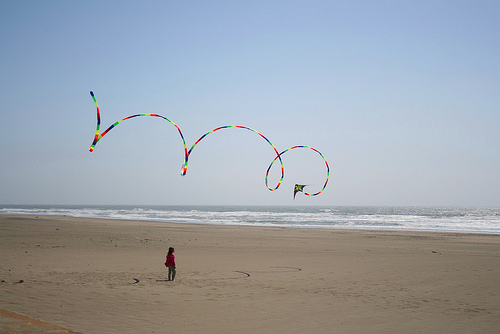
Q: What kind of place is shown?
A: It is a beach.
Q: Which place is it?
A: It is a beach.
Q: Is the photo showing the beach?
A: Yes, it is showing the beach.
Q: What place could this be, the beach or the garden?
A: It is the beach.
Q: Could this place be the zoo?
A: No, it is the beach.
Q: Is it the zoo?
A: No, it is the beach.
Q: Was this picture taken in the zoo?
A: No, the picture was taken in the beach.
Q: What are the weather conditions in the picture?
A: It is clear.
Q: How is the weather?
A: It is clear.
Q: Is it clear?
A: Yes, it is clear.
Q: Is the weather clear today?
A: Yes, it is clear.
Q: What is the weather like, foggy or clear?
A: It is clear.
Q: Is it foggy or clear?
A: It is clear.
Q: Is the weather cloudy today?
A: No, it is clear.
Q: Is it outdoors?
A: Yes, it is outdoors.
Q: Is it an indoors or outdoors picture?
A: It is outdoors.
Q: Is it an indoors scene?
A: No, it is outdoors.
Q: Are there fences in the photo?
A: No, there are no fences.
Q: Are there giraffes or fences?
A: No, there are no fences or giraffes.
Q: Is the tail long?
A: Yes, the tail is long.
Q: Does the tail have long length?
A: Yes, the tail is long.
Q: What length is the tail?
A: The tail is long.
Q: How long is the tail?
A: The tail is long.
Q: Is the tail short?
A: No, the tail is long.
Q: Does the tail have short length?
A: No, the tail is long.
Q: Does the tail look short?
A: No, the tail is long.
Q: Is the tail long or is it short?
A: The tail is long.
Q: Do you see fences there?
A: No, there are no fences.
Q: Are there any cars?
A: No, there are no cars.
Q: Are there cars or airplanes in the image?
A: No, there are no cars or airplanes.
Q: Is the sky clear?
A: Yes, the sky is clear.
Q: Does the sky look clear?
A: Yes, the sky is clear.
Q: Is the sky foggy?
A: No, the sky is clear.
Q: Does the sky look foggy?
A: No, the sky is clear.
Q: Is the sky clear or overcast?
A: The sky is clear.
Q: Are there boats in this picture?
A: No, there are no boats.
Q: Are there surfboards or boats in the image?
A: No, there are no boats or surfboards.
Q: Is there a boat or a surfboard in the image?
A: No, there are no boats or surfboards.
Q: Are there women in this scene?
A: Yes, there is a woman.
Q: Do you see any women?
A: Yes, there is a woman.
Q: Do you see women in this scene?
A: Yes, there is a woman.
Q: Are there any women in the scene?
A: Yes, there is a woman.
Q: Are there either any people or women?
A: Yes, there is a woman.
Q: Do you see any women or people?
A: Yes, there is a woman.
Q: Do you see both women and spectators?
A: No, there is a woman but no spectators.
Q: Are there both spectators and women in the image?
A: No, there is a woman but no spectators.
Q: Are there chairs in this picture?
A: No, there are no chairs.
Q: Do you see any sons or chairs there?
A: No, there are no chairs or sons.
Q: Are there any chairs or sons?
A: No, there are no chairs or sons.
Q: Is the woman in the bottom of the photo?
A: Yes, the woman is in the bottom of the image.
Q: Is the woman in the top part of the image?
A: No, the woman is in the bottom of the image.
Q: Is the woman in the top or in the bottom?
A: The woman is in the bottom of the image.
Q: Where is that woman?
A: The woman is on the sea shore.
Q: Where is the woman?
A: The woman is on the sea shore.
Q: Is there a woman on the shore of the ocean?
A: Yes, there is a woman on the sea shore.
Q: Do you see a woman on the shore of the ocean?
A: Yes, there is a woman on the sea shore.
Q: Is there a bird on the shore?
A: No, there is a woman on the shore.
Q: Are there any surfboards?
A: No, there are no surfboards.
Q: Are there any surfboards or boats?
A: No, there are no surfboards or boats.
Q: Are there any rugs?
A: No, there are no rugs.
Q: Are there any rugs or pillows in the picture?
A: No, there are no rugs or pillows.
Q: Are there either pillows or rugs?
A: No, there are no rugs or pillows.